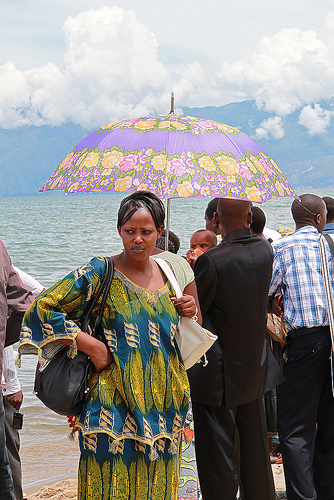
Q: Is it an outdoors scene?
A: Yes, it is outdoors.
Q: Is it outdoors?
A: Yes, it is outdoors.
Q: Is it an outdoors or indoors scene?
A: It is outdoors.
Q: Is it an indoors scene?
A: No, it is outdoors.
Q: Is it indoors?
A: No, it is outdoors.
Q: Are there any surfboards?
A: No, there are no surfboards.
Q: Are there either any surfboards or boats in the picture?
A: No, there are no surfboards or boats.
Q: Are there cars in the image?
A: No, there are no cars.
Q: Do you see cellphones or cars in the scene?
A: No, there are no cars or cellphones.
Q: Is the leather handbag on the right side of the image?
A: No, the handbag is on the left of the image.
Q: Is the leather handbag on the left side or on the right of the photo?
A: The handbag is on the left of the image.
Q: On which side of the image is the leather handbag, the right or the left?
A: The handbag is on the left of the image.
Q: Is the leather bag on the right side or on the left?
A: The handbag is on the left of the image.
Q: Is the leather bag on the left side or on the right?
A: The handbag is on the left of the image.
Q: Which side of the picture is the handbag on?
A: The handbag is on the left of the image.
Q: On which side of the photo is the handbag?
A: The handbag is on the left of the image.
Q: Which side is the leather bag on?
A: The handbag is on the left of the image.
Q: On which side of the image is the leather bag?
A: The handbag is on the left of the image.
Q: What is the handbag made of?
A: The handbag is made of leather.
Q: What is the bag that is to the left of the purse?
A: The bag is a handbag.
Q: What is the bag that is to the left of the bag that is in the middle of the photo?
A: The bag is a handbag.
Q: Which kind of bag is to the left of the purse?
A: The bag is a handbag.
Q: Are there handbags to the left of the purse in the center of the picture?
A: Yes, there is a handbag to the left of the purse.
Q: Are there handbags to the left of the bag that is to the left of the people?
A: Yes, there is a handbag to the left of the purse.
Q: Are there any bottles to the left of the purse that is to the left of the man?
A: No, there is a handbag to the left of the purse.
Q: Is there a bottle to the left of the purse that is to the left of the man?
A: No, there is a handbag to the left of the purse.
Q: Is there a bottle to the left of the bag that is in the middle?
A: No, there is a handbag to the left of the purse.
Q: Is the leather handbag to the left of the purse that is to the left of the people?
A: Yes, the handbag is to the left of the purse.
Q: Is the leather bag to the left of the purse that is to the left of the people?
A: Yes, the handbag is to the left of the purse.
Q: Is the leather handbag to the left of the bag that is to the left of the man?
A: Yes, the handbag is to the left of the purse.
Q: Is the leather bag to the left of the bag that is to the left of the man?
A: Yes, the handbag is to the left of the purse.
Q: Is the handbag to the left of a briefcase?
A: No, the handbag is to the left of the purse.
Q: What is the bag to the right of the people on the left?
A: The bag is a handbag.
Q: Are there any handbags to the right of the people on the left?
A: Yes, there is a handbag to the right of the people.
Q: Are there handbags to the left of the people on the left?
A: No, the handbag is to the right of the people.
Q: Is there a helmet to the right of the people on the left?
A: No, there is a handbag to the right of the people.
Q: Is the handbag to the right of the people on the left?
A: Yes, the handbag is to the right of the people.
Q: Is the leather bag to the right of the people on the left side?
A: Yes, the handbag is to the right of the people.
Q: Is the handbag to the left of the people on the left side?
A: No, the handbag is to the right of the people.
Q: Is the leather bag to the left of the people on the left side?
A: No, the handbag is to the right of the people.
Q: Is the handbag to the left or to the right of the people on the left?
A: The handbag is to the right of the people.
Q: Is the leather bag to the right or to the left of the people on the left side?
A: The handbag is to the right of the people.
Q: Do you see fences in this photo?
A: No, there are no fences.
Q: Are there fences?
A: No, there are no fences.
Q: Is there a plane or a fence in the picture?
A: No, there are no fences or airplanes.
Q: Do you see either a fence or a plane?
A: No, there are no fences or airplanes.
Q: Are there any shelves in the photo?
A: No, there are no shelves.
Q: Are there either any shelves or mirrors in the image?
A: No, there are no shelves or mirrors.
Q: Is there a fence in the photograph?
A: No, there are no fences.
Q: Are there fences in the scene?
A: No, there are no fences.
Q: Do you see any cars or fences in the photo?
A: No, there are no fences or cars.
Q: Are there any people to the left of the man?
A: Yes, there are people to the left of the man.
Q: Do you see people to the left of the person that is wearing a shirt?
A: Yes, there are people to the left of the man.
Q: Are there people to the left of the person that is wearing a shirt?
A: Yes, there are people to the left of the man.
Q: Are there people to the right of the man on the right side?
A: No, the people are to the left of the man.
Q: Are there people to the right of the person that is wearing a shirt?
A: No, the people are to the left of the man.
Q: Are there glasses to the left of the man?
A: No, there are people to the left of the man.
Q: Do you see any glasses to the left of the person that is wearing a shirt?
A: No, there are people to the left of the man.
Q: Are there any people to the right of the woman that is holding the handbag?
A: Yes, there are people to the right of the woman.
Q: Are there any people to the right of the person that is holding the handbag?
A: Yes, there are people to the right of the woman.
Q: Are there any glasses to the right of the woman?
A: No, there are people to the right of the woman.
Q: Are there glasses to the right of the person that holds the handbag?
A: No, there are people to the right of the woman.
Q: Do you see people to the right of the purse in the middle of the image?
A: Yes, there are people to the right of the purse.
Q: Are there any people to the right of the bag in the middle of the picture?
A: Yes, there are people to the right of the purse.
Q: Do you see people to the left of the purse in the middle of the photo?
A: No, the people are to the right of the purse.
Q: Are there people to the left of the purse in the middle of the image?
A: No, the people are to the right of the purse.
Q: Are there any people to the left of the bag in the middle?
A: No, the people are to the right of the purse.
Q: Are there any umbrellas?
A: Yes, there is an umbrella.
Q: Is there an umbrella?
A: Yes, there is an umbrella.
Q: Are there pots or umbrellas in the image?
A: Yes, there is an umbrella.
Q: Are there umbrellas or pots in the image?
A: Yes, there is an umbrella.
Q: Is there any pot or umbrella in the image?
A: Yes, there is an umbrella.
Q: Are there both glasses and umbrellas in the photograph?
A: No, there is an umbrella but no glasses.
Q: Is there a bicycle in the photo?
A: No, there are no bicycles.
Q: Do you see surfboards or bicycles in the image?
A: No, there are no bicycles or surfboards.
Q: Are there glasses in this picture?
A: No, there are no glasses.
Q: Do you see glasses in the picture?
A: No, there are no glasses.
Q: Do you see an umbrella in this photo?
A: Yes, there is an umbrella.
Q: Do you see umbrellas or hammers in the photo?
A: Yes, there is an umbrella.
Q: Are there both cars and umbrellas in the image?
A: No, there is an umbrella but no cars.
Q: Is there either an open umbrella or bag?
A: Yes, there is an open umbrella.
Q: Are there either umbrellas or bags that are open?
A: Yes, the umbrella is open.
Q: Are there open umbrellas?
A: Yes, there is an open umbrella.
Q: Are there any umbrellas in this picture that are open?
A: Yes, there is an umbrella that is open.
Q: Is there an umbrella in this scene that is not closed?
A: Yes, there is a open umbrella.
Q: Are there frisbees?
A: No, there are no frisbees.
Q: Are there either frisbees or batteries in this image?
A: No, there are no frisbees or batteries.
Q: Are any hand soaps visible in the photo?
A: No, there are no hand soaps.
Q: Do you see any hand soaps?
A: No, there are no hand soaps.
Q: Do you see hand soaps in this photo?
A: No, there are no hand soaps.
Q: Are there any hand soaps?
A: No, there are no hand soaps.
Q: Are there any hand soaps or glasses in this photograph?
A: No, there are no hand soaps or glasses.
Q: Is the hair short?
A: Yes, the hair is short.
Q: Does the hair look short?
A: Yes, the hair is short.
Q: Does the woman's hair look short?
A: Yes, the hair is short.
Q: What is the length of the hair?
A: The hair is short.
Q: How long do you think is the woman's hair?
A: The hair is short.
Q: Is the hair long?
A: No, the hair is short.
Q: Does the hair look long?
A: No, the hair is short.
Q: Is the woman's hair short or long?
A: The hair is short.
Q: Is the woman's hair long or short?
A: The hair is short.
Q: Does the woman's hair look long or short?
A: The hair is short.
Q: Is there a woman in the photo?
A: Yes, there is a woman.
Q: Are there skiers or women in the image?
A: Yes, there is a woman.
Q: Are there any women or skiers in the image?
A: Yes, there is a woman.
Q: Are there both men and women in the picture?
A: Yes, there are both a woman and a man.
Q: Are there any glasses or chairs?
A: No, there are no glasses or chairs.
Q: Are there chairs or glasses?
A: No, there are no glasses or chairs.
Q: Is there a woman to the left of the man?
A: Yes, there is a woman to the left of the man.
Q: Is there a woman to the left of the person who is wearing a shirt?
A: Yes, there is a woman to the left of the man.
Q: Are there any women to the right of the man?
A: No, the woman is to the left of the man.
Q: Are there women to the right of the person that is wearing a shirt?
A: No, the woman is to the left of the man.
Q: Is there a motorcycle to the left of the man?
A: No, there is a woman to the left of the man.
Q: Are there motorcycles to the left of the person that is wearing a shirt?
A: No, there is a woman to the left of the man.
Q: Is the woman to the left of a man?
A: Yes, the woman is to the left of a man.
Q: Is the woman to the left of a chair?
A: No, the woman is to the left of a man.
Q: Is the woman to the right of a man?
A: No, the woman is to the left of a man.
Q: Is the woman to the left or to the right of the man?
A: The woman is to the left of the man.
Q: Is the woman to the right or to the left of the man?
A: The woman is to the left of the man.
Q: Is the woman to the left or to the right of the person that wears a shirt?
A: The woman is to the left of the man.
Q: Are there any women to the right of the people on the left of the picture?
A: Yes, there is a woman to the right of the people.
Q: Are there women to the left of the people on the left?
A: No, the woman is to the right of the people.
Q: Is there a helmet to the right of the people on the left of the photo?
A: No, there is a woman to the right of the people.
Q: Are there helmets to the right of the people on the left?
A: No, there is a woman to the right of the people.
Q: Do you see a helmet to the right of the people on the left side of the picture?
A: No, there is a woman to the right of the people.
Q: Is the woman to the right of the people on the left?
A: Yes, the woman is to the right of the people.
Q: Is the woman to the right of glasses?
A: No, the woman is to the right of the people.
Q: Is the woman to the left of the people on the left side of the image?
A: No, the woman is to the right of the people.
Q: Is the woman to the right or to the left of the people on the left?
A: The woman is to the right of the people.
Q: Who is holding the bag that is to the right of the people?
A: The woman is holding the handbag.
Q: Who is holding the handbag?
A: The woman is holding the handbag.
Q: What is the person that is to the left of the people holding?
A: The woman is holding the handbag.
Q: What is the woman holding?
A: The woman is holding the handbag.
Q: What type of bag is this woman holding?
A: The woman is holding the handbag.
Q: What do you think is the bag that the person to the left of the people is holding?
A: The bag is a handbag.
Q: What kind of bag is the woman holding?
A: The woman is holding the handbag.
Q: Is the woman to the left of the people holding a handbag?
A: Yes, the woman is holding a handbag.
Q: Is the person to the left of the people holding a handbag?
A: Yes, the woman is holding a handbag.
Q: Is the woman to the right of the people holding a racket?
A: No, the woman is holding a handbag.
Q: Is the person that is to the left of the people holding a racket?
A: No, the woman is holding a handbag.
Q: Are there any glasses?
A: No, there are no glasses.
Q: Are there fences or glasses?
A: No, there are no glasses or fences.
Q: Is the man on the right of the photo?
A: Yes, the man is on the right of the image.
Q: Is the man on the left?
A: No, the man is on the right of the image.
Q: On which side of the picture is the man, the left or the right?
A: The man is on the right of the image.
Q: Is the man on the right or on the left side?
A: The man is on the right of the image.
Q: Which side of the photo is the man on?
A: The man is on the right of the image.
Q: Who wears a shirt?
A: The man wears a shirt.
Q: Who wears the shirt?
A: The man wears a shirt.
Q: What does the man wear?
A: The man wears a shirt.